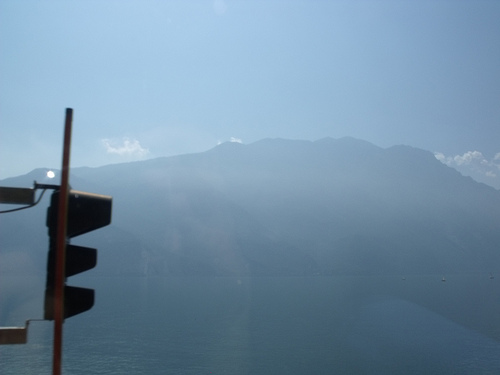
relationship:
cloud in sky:
[105, 136, 152, 157] [1, 2, 496, 213]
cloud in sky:
[422, 139, 497, 200] [1, 2, 496, 213]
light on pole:
[37, 170, 104, 329] [52, 99, 71, 371]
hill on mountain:
[210, 136, 247, 156] [0, 124, 499, 246]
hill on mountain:
[255, 134, 292, 147] [1, 131, 498, 260]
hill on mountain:
[316, 133, 336, 147] [1, 107, 497, 267]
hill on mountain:
[337, 136, 356, 148] [1, 131, 498, 260]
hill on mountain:
[353, 134, 378, 151] [0, 124, 499, 246]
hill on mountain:
[394, 139, 411, 154] [0, 124, 499, 246]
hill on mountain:
[413, 143, 434, 161] [0, 137, 499, 245]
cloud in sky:
[434, 143, 499, 180] [0, 3, 496, 186]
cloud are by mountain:
[105, 136, 152, 157] [2, 141, 487, 374]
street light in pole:
[33, 183, 106, 324] [42, 101, 76, 373]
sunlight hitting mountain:
[102, 127, 261, 370] [2, 141, 487, 374]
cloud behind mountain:
[81, 134, 161, 165] [2, 141, 487, 374]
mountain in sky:
[2, 141, 487, 374] [1, 2, 496, 213]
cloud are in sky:
[105, 136, 152, 157] [1, 2, 496, 213]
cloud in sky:
[92, 129, 149, 179] [0, 3, 496, 186]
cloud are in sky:
[105, 136, 152, 157] [0, 3, 496, 186]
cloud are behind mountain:
[105, 136, 152, 157] [2, 141, 487, 374]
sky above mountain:
[0, 3, 496, 186] [2, 141, 487, 374]